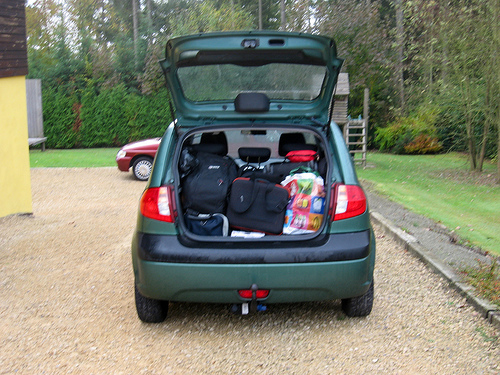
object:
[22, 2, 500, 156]
wooded area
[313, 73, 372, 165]
playhouse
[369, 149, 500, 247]
lawn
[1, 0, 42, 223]
building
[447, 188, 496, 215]
area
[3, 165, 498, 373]
driveway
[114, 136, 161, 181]
car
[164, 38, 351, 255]
trunk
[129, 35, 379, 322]
car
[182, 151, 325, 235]
luggage